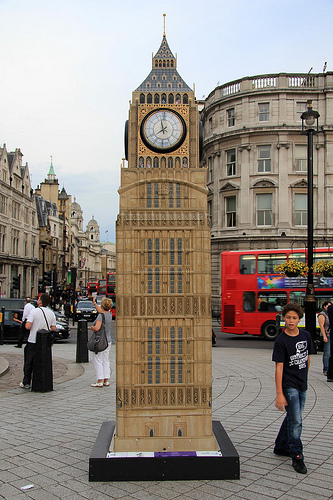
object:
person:
[270, 301, 313, 475]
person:
[87, 294, 113, 387]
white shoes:
[91, 381, 103, 387]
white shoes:
[19, 381, 29, 389]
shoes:
[91, 380, 103, 387]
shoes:
[291, 451, 307, 474]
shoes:
[273, 443, 291, 457]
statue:
[112, 8, 221, 454]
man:
[20, 293, 57, 390]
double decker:
[220, 246, 333, 341]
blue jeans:
[273, 388, 306, 458]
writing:
[289, 349, 309, 371]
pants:
[93, 342, 111, 380]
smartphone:
[89, 296, 93, 300]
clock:
[140, 106, 187, 155]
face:
[139, 106, 187, 154]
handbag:
[86, 313, 108, 355]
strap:
[36, 304, 51, 332]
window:
[256, 144, 272, 175]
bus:
[220, 246, 333, 343]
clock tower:
[115, 11, 213, 454]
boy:
[272, 300, 312, 462]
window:
[240, 252, 258, 274]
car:
[74, 300, 98, 322]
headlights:
[76, 310, 82, 314]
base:
[89, 418, 240, 480]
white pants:
[90, 339, 114, 378]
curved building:
[198, 61, 331, 317]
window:
[252, 188, 275, 227]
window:
[292, 188, 311, 226]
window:
[258, 100, 271, 122]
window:
[226, 106, 236, 128]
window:
[222, 193, 238, 230]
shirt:
[270, 329, 318, 392]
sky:
[0, 5, 332, 241]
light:
[299, 99, 320, 354]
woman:
[89, 293, 113, 387]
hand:
[92, 295, 96, 302]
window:
[256, 291, 287, 312]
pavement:
[15, 374, 315, 496]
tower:
[115, 18, 218, 453]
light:
[16, 19, 89, 148]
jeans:
[272, 388, 307, 459]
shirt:
[26, 306, 55, 342]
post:
[302, 133, 315, 352]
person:
[13, 312, 23, 324]